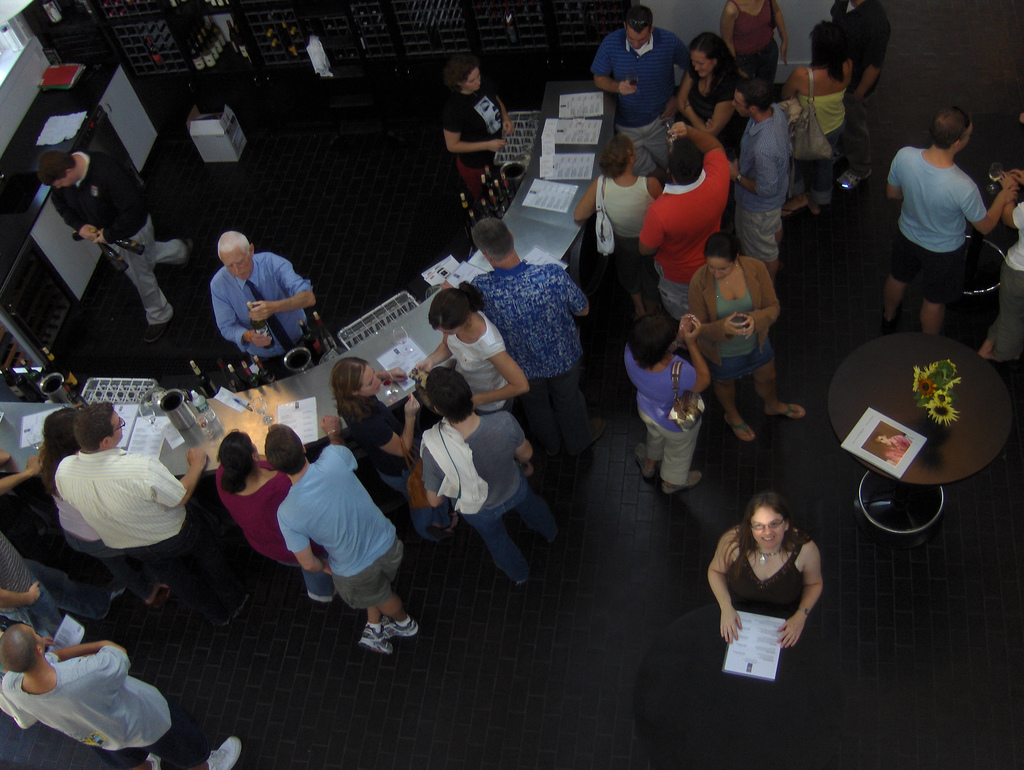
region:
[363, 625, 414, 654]
the man wearing blue top is wearing sneakers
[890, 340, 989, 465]
Sunflowers in a vase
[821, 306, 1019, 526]
A round black table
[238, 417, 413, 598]
Man wearing light blue shirt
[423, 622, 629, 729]
Black tiles on the floor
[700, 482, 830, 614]
Woman has brown hair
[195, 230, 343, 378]
Man wearing blue shirt and tie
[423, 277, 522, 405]
Woman has dark hair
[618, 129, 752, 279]
Guy has on red shirt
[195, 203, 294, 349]
Man has white hair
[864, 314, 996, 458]
Flowers on a table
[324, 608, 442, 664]
Pair of white sneakers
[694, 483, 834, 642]
A woman has on a brown tank top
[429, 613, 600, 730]
Tiles are on the floor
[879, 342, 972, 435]
Flowers on a table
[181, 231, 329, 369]
A man with a blue shirt and tie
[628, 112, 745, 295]
A guy has on a red shirt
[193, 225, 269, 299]
A man has white hair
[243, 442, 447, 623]
A man has on a light blue shirt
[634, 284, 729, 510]
A woman has a bag over her shoulder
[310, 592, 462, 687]
A guy has on sneakers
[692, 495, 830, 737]
Young woman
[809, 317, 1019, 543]
A table with flowers on it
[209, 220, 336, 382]
A bartender with a wine bottle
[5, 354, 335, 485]
wine tasteing bartop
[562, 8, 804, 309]
a group of wine tasters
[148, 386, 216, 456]
A wine chiller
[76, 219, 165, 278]
Two wine bottles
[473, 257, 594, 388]
Blue Hawain print shirt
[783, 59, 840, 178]
A beige handbag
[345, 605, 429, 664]
A pair of sneakers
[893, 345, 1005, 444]
flowers on top of a black table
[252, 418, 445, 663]
a man wearing a blue shirt and brown shorts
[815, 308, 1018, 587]
a black round table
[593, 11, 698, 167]
a man looking at a cell phone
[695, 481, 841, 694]
a woman in a black tank top looking up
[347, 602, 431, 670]
a pair of white running shoes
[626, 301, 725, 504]
a woman with a purple shirt and khaki pants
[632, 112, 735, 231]
a man wearing an orange shirt drinking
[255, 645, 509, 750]
a black brick floor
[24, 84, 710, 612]
customers and bartenders around a curved bar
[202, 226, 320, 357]
a bartender opening a bottle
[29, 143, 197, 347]
a man holding two bottles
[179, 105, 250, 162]
a white cardboard box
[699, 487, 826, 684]
a woman with a menu in front of her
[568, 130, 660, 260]
a woman with a white purse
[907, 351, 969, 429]
flowers as a table decoration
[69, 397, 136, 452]
a man with glasses on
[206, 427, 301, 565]
a woman in a purple shirt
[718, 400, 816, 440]
flip flops on a woman's feet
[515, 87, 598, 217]
menus on top of the bar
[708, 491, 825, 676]
woman looking upwards at camera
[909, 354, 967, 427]
floral arrangement with sunflowers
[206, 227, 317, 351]
bartender dressed in shirt and blue tie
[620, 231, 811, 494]
two women having conversation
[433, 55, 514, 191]
female bartender waiting for order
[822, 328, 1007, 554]
tables with foot rest rail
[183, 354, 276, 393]
alcoholic beverage bottles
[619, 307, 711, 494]
woman with white purse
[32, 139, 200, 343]
bartender opening bottles